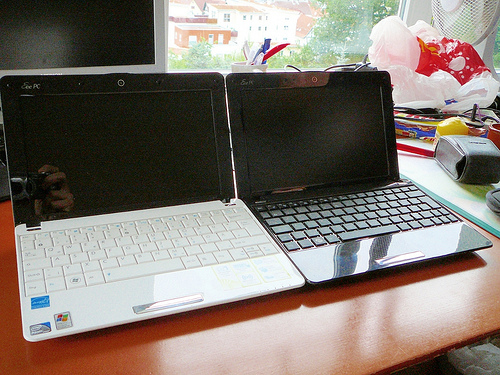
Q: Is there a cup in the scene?
A: Yes, there is a cup.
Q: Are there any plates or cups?
A: Yes, there is a cup.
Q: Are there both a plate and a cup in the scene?
A: No, there is a cup but no plates.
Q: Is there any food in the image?
A: No, there is no food.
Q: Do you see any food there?
A: No, there is no food.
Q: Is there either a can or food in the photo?
A: No, there are no food or cans.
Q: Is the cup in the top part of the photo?
A: Yes, the cup is in the top of the image.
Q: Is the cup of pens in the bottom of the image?
A: No, the cup is in the top of the image.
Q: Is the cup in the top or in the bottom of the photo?
A: The cup is in the top of the image.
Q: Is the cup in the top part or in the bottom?
A: The cup is in the top of the image.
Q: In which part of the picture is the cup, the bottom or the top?
A: The cup is in the top of the image.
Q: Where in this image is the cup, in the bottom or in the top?
A: The cup is in the top of the image.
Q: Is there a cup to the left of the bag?
A: Yes, there is a cup to the left of the bag.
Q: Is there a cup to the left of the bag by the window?
A: Yes, there is a cup to the left of the bag.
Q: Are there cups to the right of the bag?
A: No, the cup is to the left of the bag.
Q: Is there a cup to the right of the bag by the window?
A: No, the cup is to the left of the bag.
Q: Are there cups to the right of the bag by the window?
A: No, the cup is to the left of the bag.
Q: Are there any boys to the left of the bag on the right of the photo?
A: No, there is a cup to the left of the bag.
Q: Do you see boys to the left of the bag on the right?
A: No, there is a cup to the left of the bag.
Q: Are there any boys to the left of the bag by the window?
A: No, there is a cup to the left of the bag.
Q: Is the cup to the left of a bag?
A: Yes, the cup is to the left of a bag.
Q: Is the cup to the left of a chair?
A: No, the cup is to the left of a bag.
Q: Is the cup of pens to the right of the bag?
A: No, the cup is to the left of the bag.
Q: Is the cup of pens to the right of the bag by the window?
A: No, the cup is to the left of the bag.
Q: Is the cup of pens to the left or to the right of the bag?
A: The cup is to the left of the bag.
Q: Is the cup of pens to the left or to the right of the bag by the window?
A: The cup is to the left of the bag.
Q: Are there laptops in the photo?
A: Yes, there is a laptop.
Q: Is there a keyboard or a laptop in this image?
A: Yes, there is a laptop.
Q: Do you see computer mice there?
A: No, there are no computer mice.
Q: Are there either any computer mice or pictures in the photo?
A: No, there are no computer mice or pictures.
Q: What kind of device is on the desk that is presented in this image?
A: The device is a laptop.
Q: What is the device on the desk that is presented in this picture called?
A: The device is a laptop.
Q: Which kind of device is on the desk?
A: The device is a laptop.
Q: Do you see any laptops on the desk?
A: Yes, there is a laptop on the desk.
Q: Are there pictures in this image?
A: No, there are no pictures.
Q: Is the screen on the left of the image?
A: Yes, the screen is on the left of the image.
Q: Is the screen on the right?
A: No, the screen is on the left of the image.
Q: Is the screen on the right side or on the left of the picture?
A: The screen is on the left of the image.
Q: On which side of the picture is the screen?
A: The screen is on the left of the image.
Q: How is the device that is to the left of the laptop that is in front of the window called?
A: The device is a screen.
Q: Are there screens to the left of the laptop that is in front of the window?
A: Yes, there is a screen to the left of the laptop.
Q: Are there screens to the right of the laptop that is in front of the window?
A: No, the screen is to the left of the laptop.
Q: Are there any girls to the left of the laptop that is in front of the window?
A: No, there is a screen to the left of the laptop.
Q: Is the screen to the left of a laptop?
A: Yes, the screen is to the left of a laptop.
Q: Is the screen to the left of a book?
A: No, the screen is to the left of a laptop.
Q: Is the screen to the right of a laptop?
A: No, the screen is to the left of a laptop.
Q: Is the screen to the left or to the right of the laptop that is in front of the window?
A: The screen is to the left of the laptop.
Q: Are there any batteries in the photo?
A: No, there are no batteries.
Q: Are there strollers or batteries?
A: No, there are no batteries or strollers.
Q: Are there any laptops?
A: Yes, there is a laptop.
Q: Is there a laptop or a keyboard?
A: Yes, there is a laptop.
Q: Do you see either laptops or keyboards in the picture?
A: Yes, there is a laptop.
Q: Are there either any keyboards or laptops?
A: Yes, there is a laptop.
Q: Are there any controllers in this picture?
A: No, there are no controllers.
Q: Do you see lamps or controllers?
A: No, there are no controllers or lamps.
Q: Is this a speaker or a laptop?
A: This is a laptop.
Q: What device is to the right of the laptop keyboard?
A: The device is a laptop.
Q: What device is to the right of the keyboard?
A: The device is a laptop.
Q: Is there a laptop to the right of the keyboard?
A: Yes, there is a laptop to the right of the keyboard.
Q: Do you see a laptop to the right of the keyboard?
A: Yes, there is a laptop to the right of the keyboard.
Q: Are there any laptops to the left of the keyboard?
A: No, the laptop is to the right of the keyboard.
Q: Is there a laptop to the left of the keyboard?
A: No, the laptop is to the right of the keyboard.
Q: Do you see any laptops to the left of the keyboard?
A: No, the laptop is to the right of the keyboard.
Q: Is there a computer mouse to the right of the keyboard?
A: No, there is a laptop to the right of the keyboard.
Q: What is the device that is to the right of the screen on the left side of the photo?
A: The device is a laptop.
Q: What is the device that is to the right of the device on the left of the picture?
A: The device is a laptop.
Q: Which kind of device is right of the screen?
A: The device is a laptop.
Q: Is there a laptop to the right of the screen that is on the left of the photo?
A: Yes, there is a laptop to the right of the screen.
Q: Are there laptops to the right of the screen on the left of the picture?
A: Yes, there is a laptop to the right of the screen.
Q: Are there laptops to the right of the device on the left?
A: Yes, there is a laptop to the right of the screen.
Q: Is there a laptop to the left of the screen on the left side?
A: No, the laptop is to the right of the screen.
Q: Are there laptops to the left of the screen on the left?
A: No, the laptop is to the right of the screen.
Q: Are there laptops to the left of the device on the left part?
A: No, the laptop is to the right of the screen.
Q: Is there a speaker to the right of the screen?
A: No, there is a laptop to the right of the screen.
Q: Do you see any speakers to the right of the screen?
A: No, there is a laptop to the right of the screen.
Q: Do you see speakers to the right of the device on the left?
A: No, there is a laptop to the right of the screen.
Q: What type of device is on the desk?
A: The device is a laptop.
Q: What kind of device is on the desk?
A: The device is a laptop.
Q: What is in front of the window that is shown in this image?
A: The laptop is in front of the window.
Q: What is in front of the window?
A: The laptop is in front of the window.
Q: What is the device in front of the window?
A: The device is a laptop.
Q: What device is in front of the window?
A: The device is a laptop.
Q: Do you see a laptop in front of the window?
A: Yes, there is a laptop in front of the window.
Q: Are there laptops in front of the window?
A: Yes, there is a laptop in front of the window.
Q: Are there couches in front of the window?
A: No, there is a laptop in front of the window.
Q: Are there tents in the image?
A: No, there are no tents.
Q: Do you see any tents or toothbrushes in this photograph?
A: No, there are no tents or toothbrushes.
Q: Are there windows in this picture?
A: Yes, there is a window.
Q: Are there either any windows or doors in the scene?
A: Yes, there is a window.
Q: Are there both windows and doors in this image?
A: No, there is a window but no doors.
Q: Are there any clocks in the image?
A: No, there are no clocks.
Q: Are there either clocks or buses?
A: No, there are no clocks or buses.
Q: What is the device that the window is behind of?
A: The device is a laptop.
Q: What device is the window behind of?
A: The window is behind the laptop.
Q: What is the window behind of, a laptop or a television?
A: The window is behind a laptop.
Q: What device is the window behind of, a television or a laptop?
A: The window is behind a laptop.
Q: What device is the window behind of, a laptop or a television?
A: The window is behind a laptop.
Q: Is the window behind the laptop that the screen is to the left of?
A: Yes, the window is behind the laptop.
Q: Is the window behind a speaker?
A: No, the window is behind the laptop.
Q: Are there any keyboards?
A: Yes, there is a keyboard.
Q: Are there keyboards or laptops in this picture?
A: Yes, there is a keyboard.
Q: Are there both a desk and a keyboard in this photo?
A: Yes, there are both a keyboard and a desk.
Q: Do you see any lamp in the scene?
A: No, there are no lamps.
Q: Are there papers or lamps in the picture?
A: No, there are no lamps or papers.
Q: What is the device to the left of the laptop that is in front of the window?
A: The device is a keyboard.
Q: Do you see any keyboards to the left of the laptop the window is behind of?
A: Yes, there is a keyboard to the left of the laptop.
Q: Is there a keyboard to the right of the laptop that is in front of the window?
A: No, the keyboard is to the left of the laptop.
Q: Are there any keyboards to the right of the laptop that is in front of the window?
A: No, the keyboard is to the left of the laptop.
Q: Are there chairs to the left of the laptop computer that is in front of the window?
A: No, there is a keyboard to the left of the laptop.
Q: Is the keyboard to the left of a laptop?
A: Yes, the keyboard is to the left of a laptop.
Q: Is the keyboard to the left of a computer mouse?
A: No, the keyboard is to the left of a laptop.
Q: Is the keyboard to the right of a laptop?
A: No, the keyboard is to the left of a laptop.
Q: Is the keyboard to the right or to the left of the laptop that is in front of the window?
A: The keyboard is to the left of the laptop.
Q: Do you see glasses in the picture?
A: No, there are no glasses.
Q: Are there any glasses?
A: No, there are no glasses.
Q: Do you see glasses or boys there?
A: No, there are no glasses or boys.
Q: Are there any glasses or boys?
A: No, there are no glasses or boys.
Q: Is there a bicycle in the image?
A: No, there are no bicycles.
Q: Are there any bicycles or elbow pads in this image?
A: No, there are no bicycles or elbow pads.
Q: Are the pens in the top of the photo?
A: Yes, the pens are in the top of the image.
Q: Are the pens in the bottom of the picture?
A: No, the pens are in the top of the image.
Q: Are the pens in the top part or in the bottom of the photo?
A: The pens are in the top of the image.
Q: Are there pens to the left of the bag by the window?
A: Yes, there are pens to the left of the bag.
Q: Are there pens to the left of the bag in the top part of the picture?
A: Yes, there are pens to the left of the bag.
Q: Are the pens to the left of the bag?
A: Yes, the pens are to the left of the bag.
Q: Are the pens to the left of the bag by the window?
A: Yes, the pens are to the left of the bag.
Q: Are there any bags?
A: Yes, there is a bag.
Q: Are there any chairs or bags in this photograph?
A: Yes, there is a bag.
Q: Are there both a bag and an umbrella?
A: No, there is a bag but no umbrellas.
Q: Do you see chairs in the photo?
A: No, there are no chairs.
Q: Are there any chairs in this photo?
A: No, there are no chairs.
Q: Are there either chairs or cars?
A: No, there are no chairs or cars.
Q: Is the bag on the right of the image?
A: Yes, the bag is on the right of the image.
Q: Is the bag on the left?
A: No, the bag is on the right of the image.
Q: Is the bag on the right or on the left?
A: The bag is on the right of the image.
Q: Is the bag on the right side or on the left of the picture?
A: The bag is on the right of the image.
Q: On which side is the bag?
A: The bag is on the right of the image.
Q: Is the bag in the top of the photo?
A: Yes, the bag is in the top of the image.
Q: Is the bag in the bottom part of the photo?
A: No, the bag is in the top of the image.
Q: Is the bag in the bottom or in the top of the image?
A: The bag is in the top of the image.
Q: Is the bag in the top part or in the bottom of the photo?
A: The bag is in the top of the image.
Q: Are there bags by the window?
A: Yes, there is a bag by the window.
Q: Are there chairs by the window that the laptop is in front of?
A: No, there is a bag by the window.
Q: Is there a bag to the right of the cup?
A: Yes, there is a bag to the right of the cup.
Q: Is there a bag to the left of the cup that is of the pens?
A: No, the bag is to the right of the cup.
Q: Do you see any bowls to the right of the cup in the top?
A: No, there is a bag to the right of the cup.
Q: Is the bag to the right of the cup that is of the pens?
A: Yes, the bag is to the right of the cup.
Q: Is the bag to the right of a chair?
A: No, the bag is to the right of the cup.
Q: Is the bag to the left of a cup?
A: No, the bag is to the right of a cup.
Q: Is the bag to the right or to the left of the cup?
A: The bag is to the right of the cup.